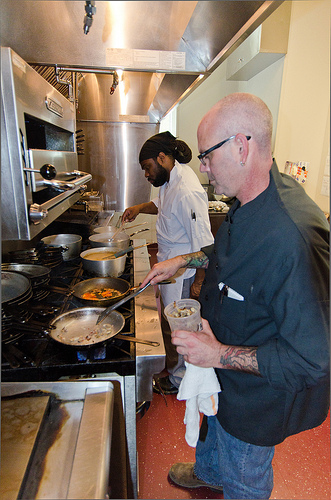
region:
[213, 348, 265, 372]
blue and red tattoo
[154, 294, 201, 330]
white container in man's hand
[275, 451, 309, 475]
pink color on the floor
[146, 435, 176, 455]
white spots on the floor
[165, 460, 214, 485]
brown leather shoes on man's foot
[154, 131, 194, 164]
black bun at end of man's hair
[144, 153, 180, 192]
full beard on man's face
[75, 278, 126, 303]
vegetables in silver skillet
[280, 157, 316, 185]
white and orange dish cloth on wall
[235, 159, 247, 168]
silver earrings in man's ear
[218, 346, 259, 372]
colorful tattoo on a man's arm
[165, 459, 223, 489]
brownish shoe on a foot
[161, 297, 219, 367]
container of food in a man's hand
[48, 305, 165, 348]
food in a silver pan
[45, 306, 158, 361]
food being cooked on a stove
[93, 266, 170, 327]
silver spatula in a cook's hand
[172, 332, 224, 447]
white towel in a cook's hand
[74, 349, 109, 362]
blue flame on a stove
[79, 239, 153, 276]
large silver pot filled with a liquidy food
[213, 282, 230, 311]
pen attached to a shirt pocket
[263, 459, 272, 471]
part of a jeans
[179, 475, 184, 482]
edge of a shoe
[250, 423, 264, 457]
part of a shirt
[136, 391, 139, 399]
part of a oven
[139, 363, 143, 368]
edge of a oven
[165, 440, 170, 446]
part of a floor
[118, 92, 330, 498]
Two men cooking in a kitchen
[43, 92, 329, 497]
Man mixing food in a frying pan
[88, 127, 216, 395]
Man stirring food in a pot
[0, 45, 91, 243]
Wall mounted silver toaster oven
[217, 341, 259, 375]
Tattoos on an arm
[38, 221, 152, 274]
Four cooking pots on a stove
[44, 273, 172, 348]
Two saute pans on a stove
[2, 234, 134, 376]
Black gas stove top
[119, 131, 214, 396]
Man wearing a white shirt and white apron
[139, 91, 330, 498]
Man wearing a baggy navy shirt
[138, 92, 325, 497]
White chef in a kitchen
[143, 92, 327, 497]
Male chef in a kitchen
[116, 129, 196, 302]
Black chef in a kitchen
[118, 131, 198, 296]
Male chef in a kitchen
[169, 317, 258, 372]
Man with a tattoo on left arm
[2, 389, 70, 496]
Grease built up on a cooktop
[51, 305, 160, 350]
Frying pan on a stove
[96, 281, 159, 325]
Silver spatula over a frying pan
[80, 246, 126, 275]
Silver pot containing liquid substance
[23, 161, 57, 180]
Black knobbed crank on an oven